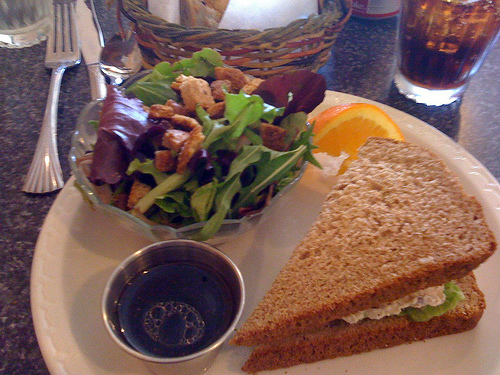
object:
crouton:
[179, 79, 213, 109]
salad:
[74, 46, 328, 243]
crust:
[227, 243, 496, 373]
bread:
[230, 137, 498, 374]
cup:
[82, 231, 250, 365]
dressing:
[127, 264, 219, 334]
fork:
[15, 1, 82, 195]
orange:
[302, 101, 404, 177]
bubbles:
[132, 292, 216, 347]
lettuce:
[407, 280, 464, 331]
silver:
[104, 38, 134, 71]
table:
[0, 0, 497, 374]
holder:
[115, 232, 225, 266]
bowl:
[73, 128, 298, 234]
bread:
[179, 0, 228, 26]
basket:
[114, 0, 351, 80]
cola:
[401, 2, 496, 84]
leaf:
[253, 65, 327, 115]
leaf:
[212, 88, 264, 142]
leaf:
[87, 130, 126, 189]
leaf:
[233, 142, 313, 212]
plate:
[29, 86, 497, 373]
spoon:
[98, 31, 143, 89]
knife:
[73, 2, 107, 99]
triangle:
[217, 121, 497, 373]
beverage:
[393, 4, 493, 84]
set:
[19, 9, 119, 205]